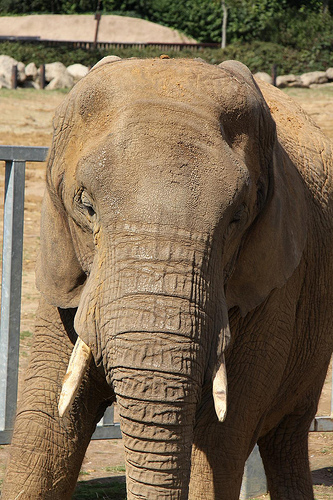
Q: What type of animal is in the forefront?
A: Elephant.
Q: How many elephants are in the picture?
A: One.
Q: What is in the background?
A: Trees.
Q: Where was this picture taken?
A: Zoo.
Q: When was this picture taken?
A: Last month.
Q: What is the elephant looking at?
A: The camera.